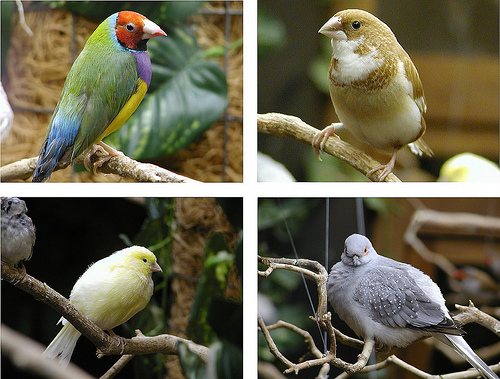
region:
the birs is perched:
[311, 234, 462, 351]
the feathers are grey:
[333, 234, 445, 358]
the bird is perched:
[36, 227, 183, 338]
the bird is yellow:
[64, 228, 177, 329]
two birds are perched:
[1, 198, 183, 335]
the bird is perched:
[60, 12, 188, 168]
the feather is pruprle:
[134, 58, 157, 84]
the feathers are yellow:
[123, 89, 135, 125]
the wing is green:
[78, 71, 119, 136]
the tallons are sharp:
[77, 150, 137, 180]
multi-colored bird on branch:
[28, 7, 168, 183]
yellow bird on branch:
[47, 240, 158, 370]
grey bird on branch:
[330, 237, 479, 377]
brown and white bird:
[315, 5, 436, 166]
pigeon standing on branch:
[333, 235, 498, 377]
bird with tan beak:
[303, 8, 431, 173]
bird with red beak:
[41, 11, 165, 181]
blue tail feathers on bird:
[31, 108, 78, 183]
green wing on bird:
[81, 56, 133, 155]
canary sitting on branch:
[48, 245, 160, 365]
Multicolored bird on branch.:
[20, 11, 172, 178]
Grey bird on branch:
[325, 235, 498, 373]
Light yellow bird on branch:
[40, 233, 166, 361]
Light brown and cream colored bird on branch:
[301, 3, 431, 181]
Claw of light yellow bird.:
[110, 321, 125, 351]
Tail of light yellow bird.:
[40, 315, 85, 365]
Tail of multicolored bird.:
[25, 131, 60, 180]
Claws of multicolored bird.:
[77, 135, 127, 171]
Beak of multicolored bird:
[140, 16, 163, 37]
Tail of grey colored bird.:
[437, 321, 497, 377]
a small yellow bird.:
[32, 240, 181, 375]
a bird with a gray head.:
[328, 222, 391, 272]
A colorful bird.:
[18, 8, 176, 180]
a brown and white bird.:
[309, 9, 434, 185]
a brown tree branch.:
[258, 92, 407, 185]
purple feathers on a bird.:
[127, 47, 162, 87]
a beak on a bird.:
[150, 247, 165, 275]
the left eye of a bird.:
[360, 245, 376, 258]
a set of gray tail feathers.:
[412, 317, 496, 377]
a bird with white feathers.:
[320, 25, 390, 82]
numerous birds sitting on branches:
[25, 25, 481, 372]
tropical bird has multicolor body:
[49, 8, 141, 181]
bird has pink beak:
[132, 15, 172, 37]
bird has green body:
[25, 44, 120, 155]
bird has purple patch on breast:
[127, 58, 170, 93]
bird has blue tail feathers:
[8, 77, 63, 207]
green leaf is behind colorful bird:
[131, 27, 212, 148]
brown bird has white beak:
[320, 7, 437, 167]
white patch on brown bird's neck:
[302, 36, 367, 110]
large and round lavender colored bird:
[325, 224, 490, 375]